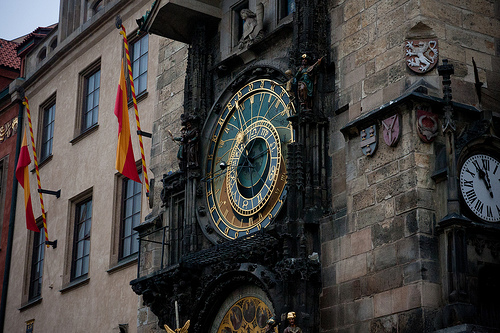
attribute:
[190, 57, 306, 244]
clock — green, gold, large, roman, black, close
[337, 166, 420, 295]
wall — brick, brown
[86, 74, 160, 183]
flag — brown, orange, red, waving, high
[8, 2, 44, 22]
sky — blue, light, dark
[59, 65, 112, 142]
window — closed, dark, black